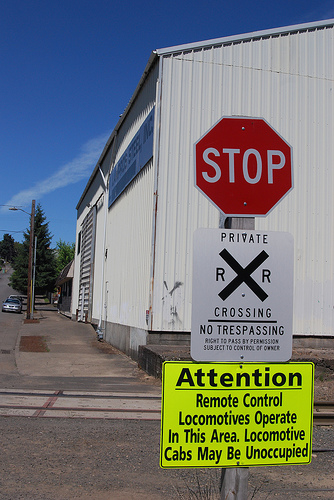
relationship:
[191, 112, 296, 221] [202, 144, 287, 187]
sign says stop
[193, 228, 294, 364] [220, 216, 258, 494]
sign on post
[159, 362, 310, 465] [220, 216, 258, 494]
sign on post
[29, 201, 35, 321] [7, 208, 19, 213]
pole has light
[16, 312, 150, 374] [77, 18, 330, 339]
sidewalk by building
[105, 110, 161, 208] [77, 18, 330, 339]
sign on building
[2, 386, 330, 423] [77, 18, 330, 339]
track by building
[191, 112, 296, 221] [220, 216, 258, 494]
sign on post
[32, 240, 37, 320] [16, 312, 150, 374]
pole by sidewalk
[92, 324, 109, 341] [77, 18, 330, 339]
meter by building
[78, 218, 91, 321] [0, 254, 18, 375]
door faces street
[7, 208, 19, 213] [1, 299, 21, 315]
light over car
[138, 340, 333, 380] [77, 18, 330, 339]
concrete by building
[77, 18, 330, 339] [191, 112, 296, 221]
building behind sign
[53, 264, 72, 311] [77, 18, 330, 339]
store by building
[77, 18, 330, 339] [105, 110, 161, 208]
building has sign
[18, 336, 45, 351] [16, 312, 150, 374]
section in sidewalk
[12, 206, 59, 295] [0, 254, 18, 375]
tree by street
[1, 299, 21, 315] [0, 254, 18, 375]
car on street